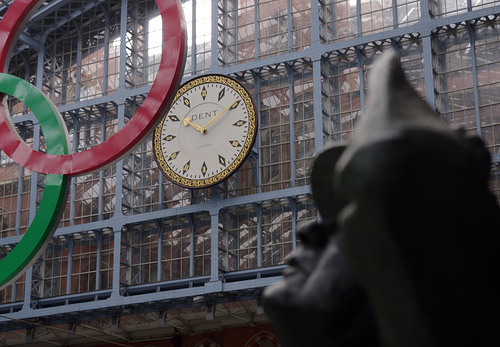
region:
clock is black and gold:
[157, 72, 284, 204]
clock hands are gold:
[172, 86, 255, 141]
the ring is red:
[0, 3, 196, 150]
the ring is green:
[0, 69, 86, 297]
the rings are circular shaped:
[0, 2, 197, 284]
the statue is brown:
[238, 46, 491, 345]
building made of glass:
[0, 1, 497, 268]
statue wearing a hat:
[287, 138, 349, 214]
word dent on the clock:
[186, 103, 223, 128]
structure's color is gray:
[205, 2, 391, 279]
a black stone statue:
[287, 109, 459, 336]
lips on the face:
[287, 252, 297, 274]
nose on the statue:
[297, 220, 324, 252]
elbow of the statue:
[348, 130, 415, 189]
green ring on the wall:
[37, 194, 72, 221]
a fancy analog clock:
[134, 69, 284, 201]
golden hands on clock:
[175, 111, 237, 138]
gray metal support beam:
[274, 44, 326, 64]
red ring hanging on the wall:
[163, 27, 190, 70]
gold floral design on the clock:
[187, 180, 203, 188]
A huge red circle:
[2, 0, 199, 177]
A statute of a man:
[261, 48, 494, 345]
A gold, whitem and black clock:
[142, 71, 262, 193]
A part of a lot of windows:
[111, 207, 227, 297]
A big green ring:
[1, 63, 86, 305]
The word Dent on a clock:
[189, 108, 218, 120]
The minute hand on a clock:
[200, 98, 240, 134]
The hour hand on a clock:
[179, 113, 205, 135]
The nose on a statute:
[290, 215, 332, 247]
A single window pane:
[300, 98, 316, 120]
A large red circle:
[1, 0, 183, 171]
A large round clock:
[153, 70, 258, 187]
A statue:
[253, 46, 498, 336]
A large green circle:
[0, 70, 70, 285]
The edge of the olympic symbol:
[0, 0, 185, 286]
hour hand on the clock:
[183, 117, 205, 134]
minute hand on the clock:
[201, 100, 239, 132]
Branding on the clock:
[191, 106, 218, 123]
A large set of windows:
[2, 2, 499, 319]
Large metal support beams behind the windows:
[2, 0, 493, 319]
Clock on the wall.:
[152, 68, 258, 200]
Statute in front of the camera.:
[240, 55, 481, 344]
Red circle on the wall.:
[7, 0, 200, 172]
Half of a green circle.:
[2, 76, 64, 304]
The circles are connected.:
[3, 49, 103, 291]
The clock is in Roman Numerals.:
[176, 91, 253, 188]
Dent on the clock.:
[178, 104, 228, 131]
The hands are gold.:
[178, 97, 247, 134]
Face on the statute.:
[281, 205, 393, 335]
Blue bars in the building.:
[13, 2, 488, 291]